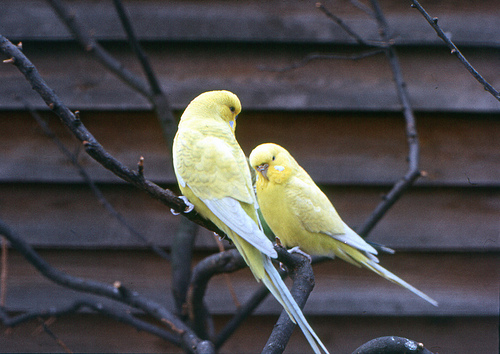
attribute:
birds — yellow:
[166, 87, 442, 330]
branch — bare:
[1, 4, 457, 337]